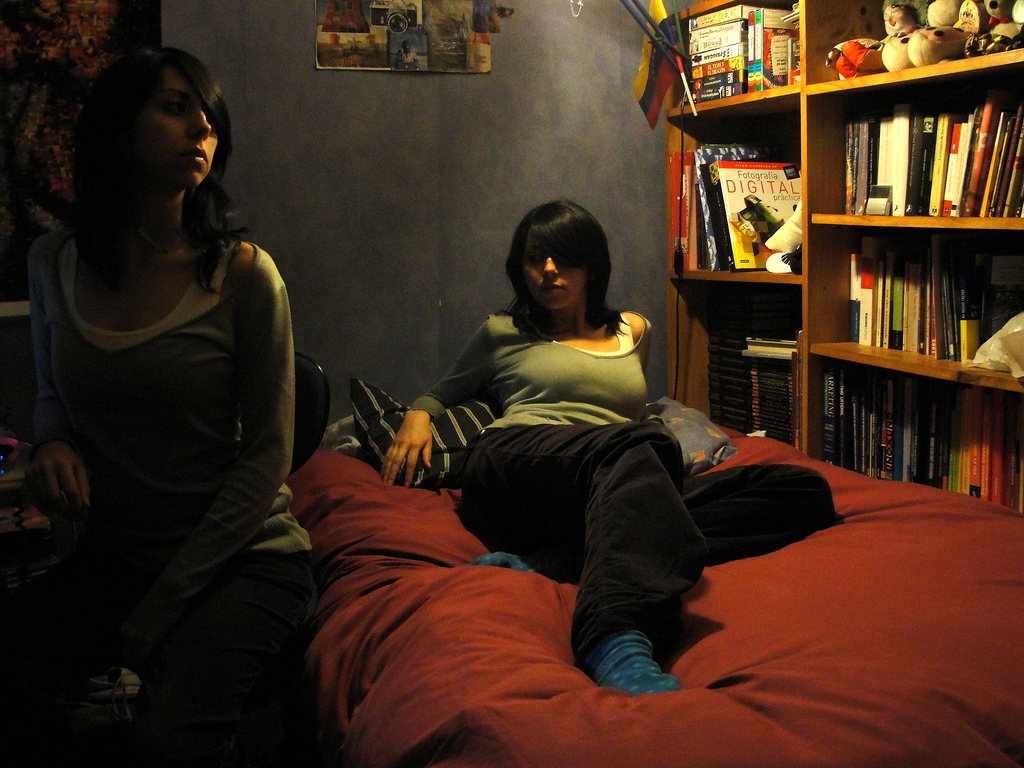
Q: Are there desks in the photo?
A: No, there are no desks.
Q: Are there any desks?
A: No, there are no desks.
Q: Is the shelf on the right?
A: Yes, the shelf is on the right of the image.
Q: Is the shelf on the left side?
A: No, the shelf is on the right of the image.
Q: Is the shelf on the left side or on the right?
A: The shelf is on the right of the image.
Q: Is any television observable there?
A: No, there are no televisions.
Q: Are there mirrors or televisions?
A: No, there are no televisions or mirrors.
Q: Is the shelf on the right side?
A: Yes, the shelf is on the right of the image.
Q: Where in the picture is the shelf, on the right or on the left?
A: The shelf is on the right of the image.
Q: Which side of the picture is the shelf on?
A: The shelf is on the right of the image.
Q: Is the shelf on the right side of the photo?
A: Yes, the shelf is on the right of the image.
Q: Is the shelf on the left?
A: No, the shelf is on the right of the image.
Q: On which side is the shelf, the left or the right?
A: The shelf is on the right of the image.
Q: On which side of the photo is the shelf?
A: The shelf is on the right of the image.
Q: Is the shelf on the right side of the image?
A: Yes, the shelf is on the right of the image.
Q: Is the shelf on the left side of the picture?
A: No, the shelf is on the right of the image.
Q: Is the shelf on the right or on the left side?
A: The shelf is on the right of the image.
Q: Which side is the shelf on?
A: The shelf is on the right of the image.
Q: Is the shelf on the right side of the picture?
A: Yes, the shelf is on the right of the image.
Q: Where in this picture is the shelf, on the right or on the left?
A: The shelf is on the right of the image.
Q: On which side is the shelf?
A: The shelf is on the right of the image.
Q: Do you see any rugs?
A: No, there are no rugs.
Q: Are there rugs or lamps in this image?
A: No, there are no rugs or lamps.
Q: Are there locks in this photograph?
A: No, there are no locks.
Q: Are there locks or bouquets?
A: No, there are no locks or bouquets.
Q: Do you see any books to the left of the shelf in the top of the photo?
A: Yes, there is a book to the left of the shelf.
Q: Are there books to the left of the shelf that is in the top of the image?
A: Yes, there is a book to the left of the shelf.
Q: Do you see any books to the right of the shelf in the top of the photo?
A: No, the book is to the left of the shelf.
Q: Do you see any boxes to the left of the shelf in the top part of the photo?
A: No, there is a book to the left of the shelf.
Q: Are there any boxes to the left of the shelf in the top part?
A: No, there is a book to the left of the shelf.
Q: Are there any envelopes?
A: No, there are no envelopes.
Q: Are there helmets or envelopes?
A: No, there are no envelopes or helmets.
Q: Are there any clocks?
A: No, there are no clocks.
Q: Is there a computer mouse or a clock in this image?
A: No, there are no clocks or computer mice.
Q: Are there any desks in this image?
A: No, there are no desks.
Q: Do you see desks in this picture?
A: No, there are no desks.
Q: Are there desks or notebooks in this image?
A: No, there are no desks or notebooks.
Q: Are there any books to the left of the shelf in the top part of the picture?
A: Yes, there is a book to the left of the shelf.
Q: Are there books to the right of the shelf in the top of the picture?
A: No, the book is to the left of the shelf.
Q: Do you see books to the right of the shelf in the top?
A: No, the book is to the left of the shelf.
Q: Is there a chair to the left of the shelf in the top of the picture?
A: No, there is a book to the left of the shelf.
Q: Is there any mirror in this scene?
A: No, there are no mirrors.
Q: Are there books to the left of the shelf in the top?
A: Yes, there is a book to the left of the shelf.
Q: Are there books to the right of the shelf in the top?
A: No, the book is to the left of the shelf.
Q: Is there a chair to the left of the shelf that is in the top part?
A: No, there is a book to the left of the shelf.